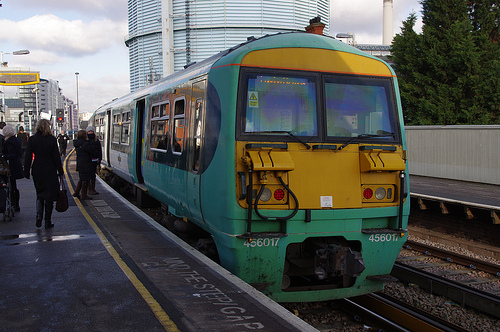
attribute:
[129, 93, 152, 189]
door —  open,  of   train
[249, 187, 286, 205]
headlights —   train's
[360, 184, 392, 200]
headlights —   train's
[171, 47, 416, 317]
train — green , yellow 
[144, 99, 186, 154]
windows —  two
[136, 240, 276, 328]
paint —  yellow and white ,  of platform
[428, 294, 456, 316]
stone — small 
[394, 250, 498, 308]
plumbing — white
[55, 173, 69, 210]
hand bag — for hand 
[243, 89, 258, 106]
sticker —  yellow and black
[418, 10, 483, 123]
tree — green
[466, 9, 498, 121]
tree — green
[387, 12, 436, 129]
tree — green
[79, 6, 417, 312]
train —  yellow and green, red, green, yellow,  green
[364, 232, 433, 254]
numbers — white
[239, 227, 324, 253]
numbers — white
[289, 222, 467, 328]
train tracks — brown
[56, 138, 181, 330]
line — yellow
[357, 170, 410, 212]
head light — train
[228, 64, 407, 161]
windshield —  clear,  with black border,  of train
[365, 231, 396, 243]
number —  white